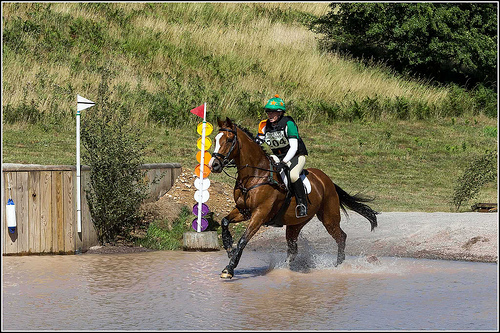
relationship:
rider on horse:
[253, 86, 322, 196] [207, 122, 352, 288]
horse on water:
[207, 122, 352, 288] [130, 254, 227, 325]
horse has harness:
[207, 122, 352, 288] [204, 142, 281, 193]